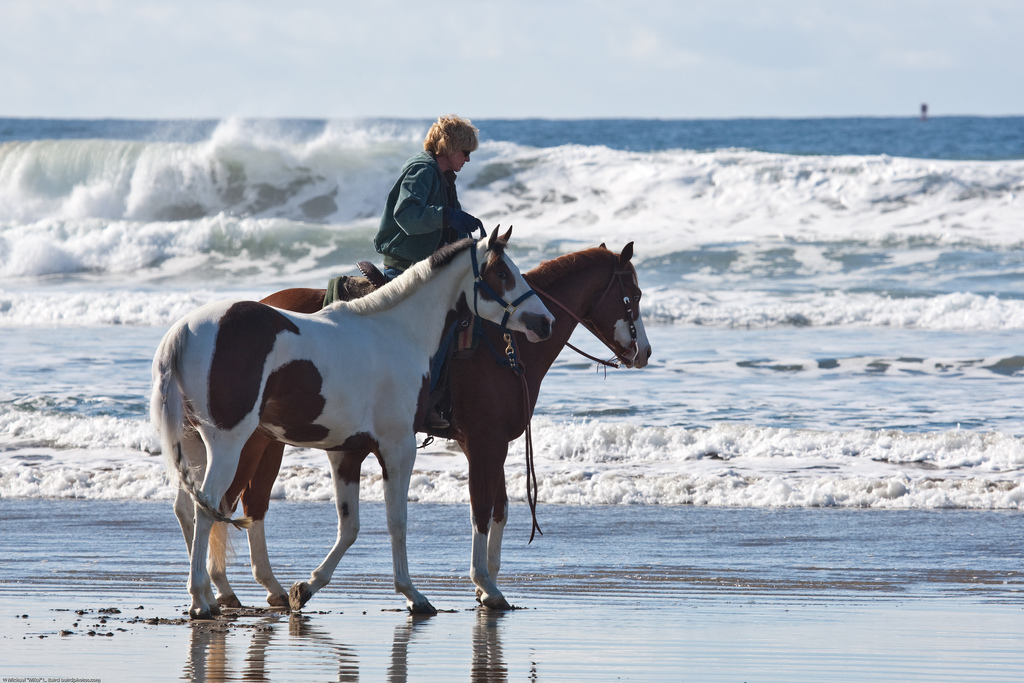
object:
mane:
[336, 237, 483, 317]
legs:
[187, 414, 244, 616]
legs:
[211, 434, 290, 615]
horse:
[205, 237, 652, 611]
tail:
[150, 322, 256, 533]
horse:
[153, 224, 563, 622]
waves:
[0, 118, 1022, 277]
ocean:
[0, 112, 1022, 523]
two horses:
[143, 223, 653, 619]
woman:
[372, 113, 481, 275]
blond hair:
[424, 113, 481, 160]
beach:
[0, 422, 1022, 679]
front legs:
[288, 443, 433, 612]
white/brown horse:
[147, 220, 557, 619]